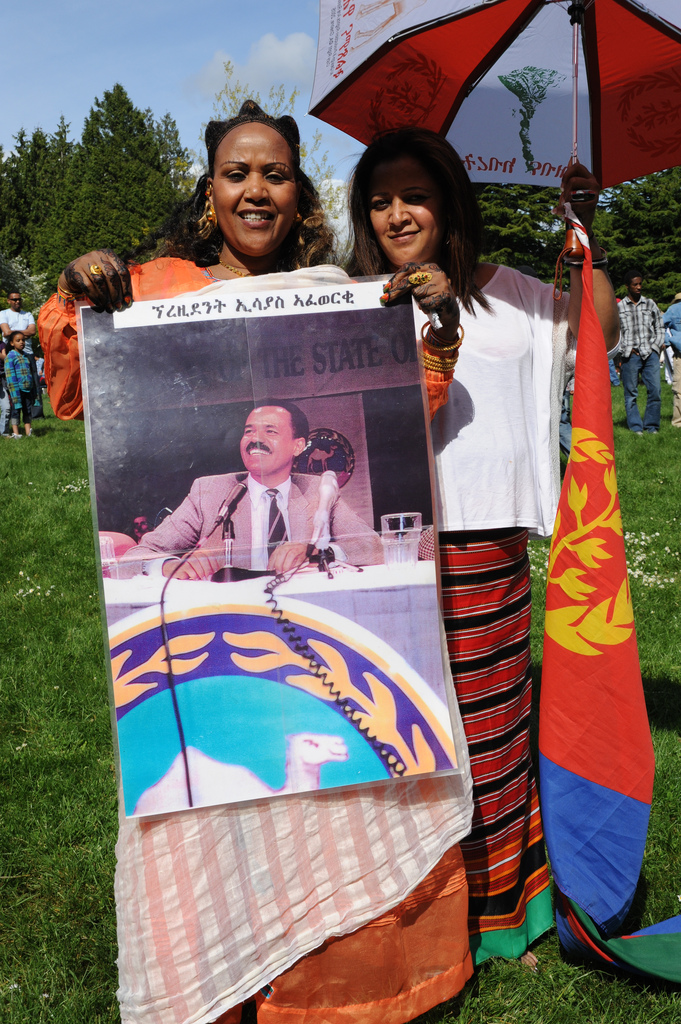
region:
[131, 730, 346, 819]
a white camel on a poster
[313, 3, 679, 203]
a red and white umbrella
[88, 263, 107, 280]
a round gold ring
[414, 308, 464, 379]
gold bracelets on a woman's wrist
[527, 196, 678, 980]
an orange, green, blue and yellow flag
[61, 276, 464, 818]
a poster of a dark skinned man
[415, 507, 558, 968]
a multi-colored woman's skirt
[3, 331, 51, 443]
a young boy standing behind the woman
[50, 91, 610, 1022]
Two women standing outside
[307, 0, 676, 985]
Woman holding a red and white umbrella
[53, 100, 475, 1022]
Woman holding a poster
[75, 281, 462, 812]
Poster of a man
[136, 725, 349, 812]
Camel on a poster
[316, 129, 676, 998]
Woman holding a banner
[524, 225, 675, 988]
Red, yellow, blue and green banner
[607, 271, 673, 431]
Man standing in the background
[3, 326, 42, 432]
Child standing in the background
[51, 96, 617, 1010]
Two women smiling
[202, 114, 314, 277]
the head of a woman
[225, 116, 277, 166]
the forehead of a woman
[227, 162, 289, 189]
the eyes of a woman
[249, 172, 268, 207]
the nose of a woman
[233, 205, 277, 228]
the mouth of a woman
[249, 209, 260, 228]
the teeth of a woman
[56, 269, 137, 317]
the fingers of a woman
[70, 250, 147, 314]
the hand of a woman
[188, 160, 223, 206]
the ear of a woman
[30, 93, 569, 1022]
Two women in long clothing.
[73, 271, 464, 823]
A sign with Arabic writing.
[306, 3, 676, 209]
A red and white umbrella.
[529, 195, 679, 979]
A flag.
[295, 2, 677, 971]
A woman holding an umbrella.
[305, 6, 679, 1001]
A woman holding an umbrella and a flag.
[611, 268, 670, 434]
A man in jeans and a plaid shirt.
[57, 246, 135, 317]
A woman's tattooed hand.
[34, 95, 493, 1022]
A woman in a long skirt.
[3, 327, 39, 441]
A child standing in the grass.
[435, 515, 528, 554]
stripe on woman's dress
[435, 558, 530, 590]
stripe on woman's dress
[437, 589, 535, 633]
stripe on woman's dress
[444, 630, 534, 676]
stripe on woman's dress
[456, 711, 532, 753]
stripe on woman's dress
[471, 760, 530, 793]
stripe on woman's dress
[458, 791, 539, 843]
stripe on woman's dress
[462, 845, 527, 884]
stripe on woman's dress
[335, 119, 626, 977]
woman holding an umbrella and a flag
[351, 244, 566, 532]
white shirt on woman holding flag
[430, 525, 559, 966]
colorful skirt on woman holding flag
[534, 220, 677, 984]
flag that the woman with the white shirt is holding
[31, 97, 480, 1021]
woman in orange holding a poster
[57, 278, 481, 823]
poster the woman in orange is holding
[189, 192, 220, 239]
ear ring in womans ear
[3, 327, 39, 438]
child standing in back ground with father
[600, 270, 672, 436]
man of african descent in the background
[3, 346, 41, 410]
childs blue and green sweater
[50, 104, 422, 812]
woman holding up a picture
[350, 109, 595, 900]
woman holding a umbrella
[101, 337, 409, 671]
picture of a man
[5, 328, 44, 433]
little kid wearing a plaid shirt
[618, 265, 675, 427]
man wearing a plaid shirt